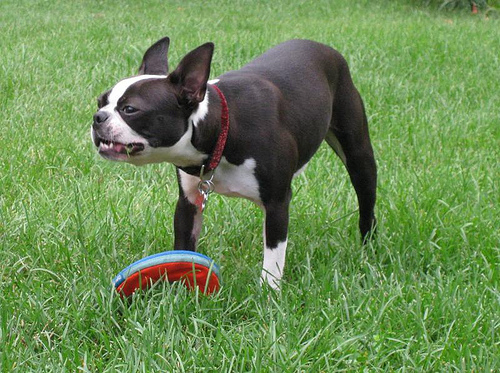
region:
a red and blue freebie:
[112, 248, 229, 305]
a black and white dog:
[95, 35, 380, 298]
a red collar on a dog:
[199, 83, 225, 188]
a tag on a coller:
[189, 188, 216, 218]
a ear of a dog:
[170, 39, 218, 106]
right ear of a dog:
[135, 38, 173, 80]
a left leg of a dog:
[258, 187, 291, 299]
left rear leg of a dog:
[343, 97, 380, 248]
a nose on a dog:
[92, 105, 107, 133]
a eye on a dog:
[118, 101, 139, 121]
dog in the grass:
[44, 33, 390, 218]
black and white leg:
[243, 190, 313, 291]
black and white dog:
[46, 7, 390, 248]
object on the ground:
[93, 228, 224, 323]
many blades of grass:
[303, 260, 443, 363]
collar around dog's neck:
[178, 90, 274, 186]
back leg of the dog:
[331, 137, 418, 244]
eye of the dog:
[113, 96, 151, 128]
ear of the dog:
[170, 37, 224, 108]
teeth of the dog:
[95, 133, 120, 156]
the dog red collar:
[203, 84, 226, 179]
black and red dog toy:
[115, 252, 217, 301]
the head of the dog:
[83, 41, 199, 167]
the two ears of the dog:
[143, 34, 210, 94]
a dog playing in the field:
[1, 27, 498, 372]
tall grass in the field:
[279, 287, 483, 369]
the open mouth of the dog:
[93, 128, 146, 160]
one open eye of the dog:
[121, 102, 138, 117]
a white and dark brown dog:
[93, 65, 390, 267]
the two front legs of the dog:
[172, 177, 292, 284]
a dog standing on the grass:
[44, 24, 419, 275]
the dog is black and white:
[56, 20, 415, 279]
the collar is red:
[159, 60, 244, 217]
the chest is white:
[187, 151, 254, 212]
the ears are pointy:
[129, 21, 221, 118]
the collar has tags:
[171, 160, 223, 222]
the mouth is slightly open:
[75, 126, 145, 168]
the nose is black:
[76, 101, 118, 135]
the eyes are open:
[80, 86, 152, 118]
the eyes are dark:
[94, 87, 144, 118]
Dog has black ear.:
[166, 41, 234, 116]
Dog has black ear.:
[124, 36, 191, 79]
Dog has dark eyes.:
[88, 90, 153, 136]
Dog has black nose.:
[84, 107, 109, 127]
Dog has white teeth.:
[86, 133, 119, 151]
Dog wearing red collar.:
[199, 108, 251, 187]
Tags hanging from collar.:
[189, 186, 233, 225]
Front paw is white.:
[255, 231, 291, 327]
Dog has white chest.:
[195, 156, 245, 206]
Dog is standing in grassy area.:
[81, 69, 350, 334]